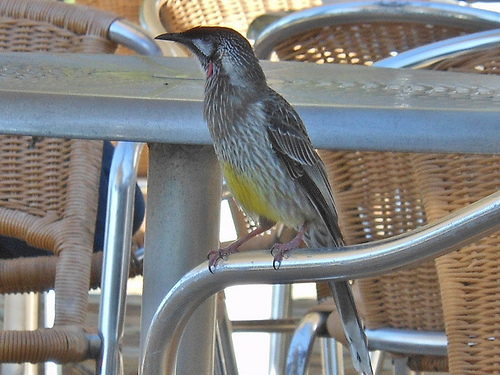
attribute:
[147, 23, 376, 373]
bird — here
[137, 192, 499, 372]
chair — here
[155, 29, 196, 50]
beak — black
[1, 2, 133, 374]
chair — here, woven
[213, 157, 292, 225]
belly — yellow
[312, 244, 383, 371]
tailfeathers — long